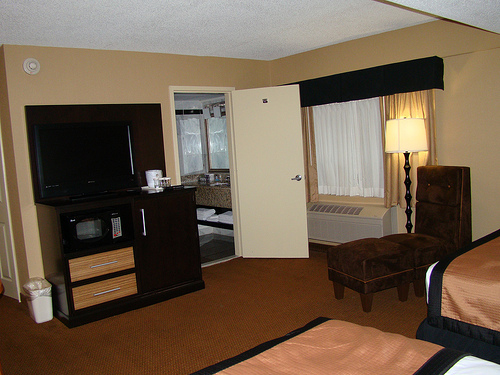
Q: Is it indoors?
A: Yes, it is indoors.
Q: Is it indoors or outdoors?
A: It is indoors.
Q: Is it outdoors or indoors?
A: It is indoors.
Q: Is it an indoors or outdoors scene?
A: It is indoors.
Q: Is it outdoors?
A: No, it is indoors.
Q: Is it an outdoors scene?
A: No, it is indoors.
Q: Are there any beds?
A: Yes, there is a bed.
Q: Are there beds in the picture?
A: Yes, there is a bed.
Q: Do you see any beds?
A: Yes, there is a bed.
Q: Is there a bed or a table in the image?
A: Yes, there is a bed.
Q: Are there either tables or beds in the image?
A: Yes, there is a bed.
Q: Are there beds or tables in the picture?
A: Yes, there is a bed.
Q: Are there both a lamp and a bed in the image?
A: Yes, there are both a bed and a lamp.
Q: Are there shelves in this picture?
A: No, there are no shelves.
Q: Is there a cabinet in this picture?
A: Yes, there is a cabinet.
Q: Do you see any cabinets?
A: Yes, there is a cabinet.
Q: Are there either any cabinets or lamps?
A: Yes, there is a cabinet.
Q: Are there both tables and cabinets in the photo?
A: No, there is a cabinet but no tables.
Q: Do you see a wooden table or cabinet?
A: Yes, there is a wood cabinet.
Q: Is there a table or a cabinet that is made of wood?
A: Yes, the cabinet is made of wood.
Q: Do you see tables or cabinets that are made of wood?
A: Yes, the cabinet is made of wood.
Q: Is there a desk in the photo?
A: No, there are no desks.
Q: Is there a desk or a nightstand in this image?
A: No, there are no desks or nightstands.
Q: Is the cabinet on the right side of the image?
A: No, the cabinet is on the left of the image.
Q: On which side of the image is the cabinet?
A: The cabinet is on the left of the image.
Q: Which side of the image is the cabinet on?
A: The cabinet is on the left of the image.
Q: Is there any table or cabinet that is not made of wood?
A: No, there is a cabinet but it is made of wood.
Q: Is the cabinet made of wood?
A: Yes, the cabinet is made of wood.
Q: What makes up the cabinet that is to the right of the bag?
A: The cabinet is made of wood.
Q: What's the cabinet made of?
A: The cabinet is made of wood.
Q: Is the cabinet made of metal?
A: No, the cabinet is made of wood.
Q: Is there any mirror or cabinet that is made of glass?
A: No, there is a cabinet but it is made of wood.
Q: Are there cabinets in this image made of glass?
A: No, there is a cabinet but it is made of wood.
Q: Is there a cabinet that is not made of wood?
A: No, there is a cabinet but it is made of wood.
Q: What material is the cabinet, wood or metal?
A: The cabinet is made of wood.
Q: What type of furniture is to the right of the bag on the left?
A: The piece of furniture is a cabinet.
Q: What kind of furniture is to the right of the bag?
A: The piece of furniture is a cabinet.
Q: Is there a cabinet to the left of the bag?
A: No, the cabinet is to the right of the bag.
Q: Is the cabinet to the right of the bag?
A: Yes, the cabinet is to the right of the bag.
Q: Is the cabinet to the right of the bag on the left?
A: Yes, the cabinet is to the right of the bag.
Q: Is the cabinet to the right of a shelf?
A: No, the cabinet is to the right of the bag.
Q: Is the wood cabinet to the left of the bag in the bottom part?
A: No, the cabinet is to the right of the bag.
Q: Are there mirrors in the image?
A: No, there are no mirrors.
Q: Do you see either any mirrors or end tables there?
A: No, there are no mirrors or end tables.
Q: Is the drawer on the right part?
A: No, the drawer is on the left of the image.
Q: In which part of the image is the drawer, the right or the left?
A: The drawer is on the left of the image.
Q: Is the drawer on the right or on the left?
A: The drawer is on the left of the image.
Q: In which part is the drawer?
A: The drawer is on the left of the image.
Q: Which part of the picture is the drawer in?
A: The drawer is on the left of the image.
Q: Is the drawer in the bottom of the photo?
A: Yes, the drawer is in the bottom of the image.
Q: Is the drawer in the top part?
A: No, the drawer is in the bottom of the image.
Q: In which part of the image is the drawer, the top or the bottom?
A: The drawer is in the bottom of the image.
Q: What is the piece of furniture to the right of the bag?
A: The piece of furniture is a drawer.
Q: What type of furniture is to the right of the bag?
A: The piece of furniture is a drawer.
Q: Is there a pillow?
A: No, there are no pillows.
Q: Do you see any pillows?
A: No, there are no pillows.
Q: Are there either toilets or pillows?
A: No, there are no pillows or toilets.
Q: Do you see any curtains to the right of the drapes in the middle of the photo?
A: Yes, there is a curtain to the right of the drapes.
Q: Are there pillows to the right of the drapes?
A: No, there is a curtain to the right of the drapes.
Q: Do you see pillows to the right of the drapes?
A: No, there is a curtain to the right of the drapes.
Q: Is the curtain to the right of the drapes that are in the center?
A: Yes, the curtain is to the right of the drapes.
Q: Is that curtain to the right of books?
A: No, the curtain is to the right of the drapes.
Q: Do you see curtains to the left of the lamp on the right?
A: Yes, there is a curtain to the left of the lamp.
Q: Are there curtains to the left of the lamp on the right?
A: Yes, there is a curtain to the left of the lamp.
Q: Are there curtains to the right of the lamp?
A: No, the curtain is to the left of the lamp.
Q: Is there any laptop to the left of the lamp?
A: No, there is a curtain to the left of the lamp.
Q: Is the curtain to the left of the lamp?
A: Yes, the curtain is to the left of the lamp.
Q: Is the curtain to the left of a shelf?
A: No, the curtain is to the left of the lamp.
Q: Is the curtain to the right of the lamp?
A: No, the curtain is to the left of the lamp.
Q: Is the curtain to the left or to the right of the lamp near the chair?
A: The curtain is to the left of the lamp.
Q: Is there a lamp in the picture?
A: Yes, there is a lamp.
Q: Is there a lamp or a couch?
A: Yes, there is a lamp.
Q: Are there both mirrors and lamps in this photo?
A: No, there is a lamp but no mirrors.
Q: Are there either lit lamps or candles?
A: Yes, there is a lit lamp.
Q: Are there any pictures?
A: No, there are no pictures.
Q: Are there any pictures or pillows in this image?
A: No, there are no pictures or pillows.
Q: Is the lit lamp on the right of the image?
A: Yes, the lamp is on the right of the image.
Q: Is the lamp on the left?
A: No, the lamp is on the right of the image.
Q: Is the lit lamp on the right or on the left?
A: The lamp is on the right of the image.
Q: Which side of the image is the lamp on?
A: The lamp is on the right of the image.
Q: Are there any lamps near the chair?
A: Yes, there is a lamp near the chair.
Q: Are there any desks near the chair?
A: No, there is a lamp near the chair.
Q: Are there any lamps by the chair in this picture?
A: Yes, there is a lamp by the chair.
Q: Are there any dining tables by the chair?
A: No, there is a lamp by the chair.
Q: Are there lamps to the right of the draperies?
A: Yes, there is a lamp to the right of the draperies.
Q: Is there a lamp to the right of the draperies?
A: Yes, there is a lamp to the right of the draperies.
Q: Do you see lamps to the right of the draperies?
A: Yes, there is a lamp to the right of the draperies.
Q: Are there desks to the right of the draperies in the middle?
A: No, there is a lamp to the right of the draperies.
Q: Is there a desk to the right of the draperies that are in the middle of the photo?
A: No, there is a lamp to the right of the draperies.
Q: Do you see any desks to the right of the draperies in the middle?
A: No, there is a lamp to the right of the draperies.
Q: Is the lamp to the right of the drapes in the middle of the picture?
A: Yes, the lamp is to the right of the draperies.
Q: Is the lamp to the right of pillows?
A: No, the lamp is to the right of the draperies.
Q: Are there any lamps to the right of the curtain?
A: Yes, there is a lamp to the right of the curtain.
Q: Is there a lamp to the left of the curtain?
A: No, the lamp is to the right of the curtain.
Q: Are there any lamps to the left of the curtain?
A: No, the lamp is to the right of the curtain.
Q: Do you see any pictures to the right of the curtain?
A: No, there is a lamp to the right of the curtain.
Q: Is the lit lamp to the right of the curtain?
A: Yes, the lamp is to the right of the curtain.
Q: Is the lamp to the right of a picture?
A: No, the lamp is to the right of the curtain.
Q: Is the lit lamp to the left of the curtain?
A: No, the lamp is to the right of the curtain.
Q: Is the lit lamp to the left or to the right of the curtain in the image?
A: The lamp is to the right of the curtain.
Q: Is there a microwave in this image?
A: Yes, there is a microwave.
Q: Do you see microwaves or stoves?
A: Yes, there is a microwave.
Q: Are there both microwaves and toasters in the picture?
A: No, there is a microwave but no toasters.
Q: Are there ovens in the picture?
A: No, there are no ovens.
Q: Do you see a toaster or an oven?
A: No, there are no ovens or toasters.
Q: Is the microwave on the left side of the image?
A: Yes, the microwave is on the left of the image.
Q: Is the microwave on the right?
A: No, the microwave is on the left of the image.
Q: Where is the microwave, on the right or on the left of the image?
A: The microwave is on the left of the image.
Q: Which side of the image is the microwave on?
A: The microwave is on the left of the image.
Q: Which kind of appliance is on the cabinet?
A: The appliance is a microwave.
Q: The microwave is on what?
A: The microwave is on the cabinet.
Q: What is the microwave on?
A: The microwave is on the cabinet.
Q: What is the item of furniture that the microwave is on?
A: The piece of furniture is a cabinet.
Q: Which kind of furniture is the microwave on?
A: The microwave is on the cabinet.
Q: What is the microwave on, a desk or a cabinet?
A: The microwave is on a cabinet.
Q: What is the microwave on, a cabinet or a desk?
A: The microwave is on a cabinet.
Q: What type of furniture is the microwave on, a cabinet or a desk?
A: The microwave is on a cabinet.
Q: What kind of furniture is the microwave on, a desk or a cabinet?
A: The microwave is on a cabinet.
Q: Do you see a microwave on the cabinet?
A: Yes, there is a microwave on the cabinet.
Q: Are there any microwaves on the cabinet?
A: Yes, there is a microwave on the cabinet.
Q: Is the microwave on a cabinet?
A: Yes, the microwave is on a cabinet.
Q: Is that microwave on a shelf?
A: No, the microwave is on a cabinet.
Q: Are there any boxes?
A: No, there are no boxes.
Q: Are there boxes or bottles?
A: No, there are no boxes or bottles.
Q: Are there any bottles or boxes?
A: No, there are no boxes or bottles.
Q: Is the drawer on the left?
A: Yes, the drawer is on the left of the image.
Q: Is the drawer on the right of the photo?
A: No, the drawer is on the left of the image.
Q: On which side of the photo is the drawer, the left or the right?
A: The drawer is on the left of the image.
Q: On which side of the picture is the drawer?
A: The drawer is on the left of the image.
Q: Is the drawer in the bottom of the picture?
A: Yes, the drawer is in the bottom of the image.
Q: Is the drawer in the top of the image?
A: No, the drawer is in the bottom of the image.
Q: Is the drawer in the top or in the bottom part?
A: The drawer is in the bottom of the image.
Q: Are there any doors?
A: Yes, there is a door.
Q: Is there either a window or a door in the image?
A: Yes, there is a door.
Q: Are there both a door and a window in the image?
A: Yes, there are both a door and a window.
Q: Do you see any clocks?
A: No, there are no clocks.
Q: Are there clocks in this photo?
A: No, there are no clocks.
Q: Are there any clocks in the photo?
A: No, there are no clocks.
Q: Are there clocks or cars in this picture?
A: No, there are no clocks or cars.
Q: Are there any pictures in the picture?
A: No, there are no pictures.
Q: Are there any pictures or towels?
A: No, there are no pictures or towels.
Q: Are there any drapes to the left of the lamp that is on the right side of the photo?
A: Yes, there are drapes to the left of the lamp.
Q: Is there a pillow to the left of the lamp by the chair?
A: No, there are drapes to the left of the lamp.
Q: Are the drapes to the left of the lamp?
A: Yes, the drapes are to the left of the lamp.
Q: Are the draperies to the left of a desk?
A: No, the draperies are to the left of the lamp.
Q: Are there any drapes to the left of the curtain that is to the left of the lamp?
A: Yes, there are drapes to the left of the curtain.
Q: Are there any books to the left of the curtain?
A: No, there are drapes to the left of the curtain.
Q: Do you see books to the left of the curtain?
A: No, there are drapes to the left of the curtain.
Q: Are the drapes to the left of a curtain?
A: Yes, the drapes are to the left of a curtain.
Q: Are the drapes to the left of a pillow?
A: No, the drapes are to the left of a curtain.